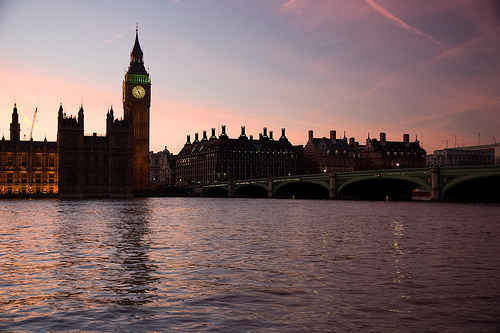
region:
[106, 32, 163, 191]
brown clock tower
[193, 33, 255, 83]
white clouds in blue sky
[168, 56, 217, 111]
white clouds in blue sky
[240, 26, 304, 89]
white clouds in blue sky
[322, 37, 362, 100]
white clouds in blue sky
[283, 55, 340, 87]
white clouds in blue sky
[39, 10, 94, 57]
white clouds in blue sky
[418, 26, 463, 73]
white clouds in blue sky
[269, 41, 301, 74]
white clouds in blue sky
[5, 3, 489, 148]
blue sky at sunset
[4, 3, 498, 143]
blue sky with streaks of white cloud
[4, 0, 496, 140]
blue sky with touches of pink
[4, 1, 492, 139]
blue sky with pink and white streaks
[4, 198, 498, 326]
still water with small ripples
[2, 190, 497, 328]
dark water with reflected light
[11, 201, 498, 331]
water with shadows cast by buildings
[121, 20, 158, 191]
tall clock tower with white face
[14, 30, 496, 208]
skyline cast against a blue and pink sky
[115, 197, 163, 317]
shadow cast by clock tower on water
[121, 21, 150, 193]
tower of the clock Big Ben in London, England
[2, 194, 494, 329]
river running in front of Big Ben with sunset reflection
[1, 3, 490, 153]
blue and pink sky of sunset over Big Ben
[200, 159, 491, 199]
bridge over river next to Big Ben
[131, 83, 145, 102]
white clock face of Big Ben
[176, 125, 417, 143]
multiple chimneys in the buildings near Big Ben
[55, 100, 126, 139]
pointed spires silhouetted in the sunset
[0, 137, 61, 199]
warm light shining on a building near Big Ben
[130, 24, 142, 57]
upper part of the tower of Big Ben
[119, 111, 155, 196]
base of the tower of Big Ben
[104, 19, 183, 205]
the big ben is visble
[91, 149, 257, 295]
the water is calm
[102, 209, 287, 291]
the water is calm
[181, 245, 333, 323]
the water is calm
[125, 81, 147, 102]
clock on side of building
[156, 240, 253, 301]
light waves on water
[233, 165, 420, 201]
bridge above water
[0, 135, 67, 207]
large brick building with lights on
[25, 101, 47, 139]
crane up in the sky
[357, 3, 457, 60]
cloud line across sky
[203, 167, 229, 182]
several street lights on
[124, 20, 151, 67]
peak of tower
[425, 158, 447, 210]
leg of bridge in water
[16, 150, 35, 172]
window on side of brick building